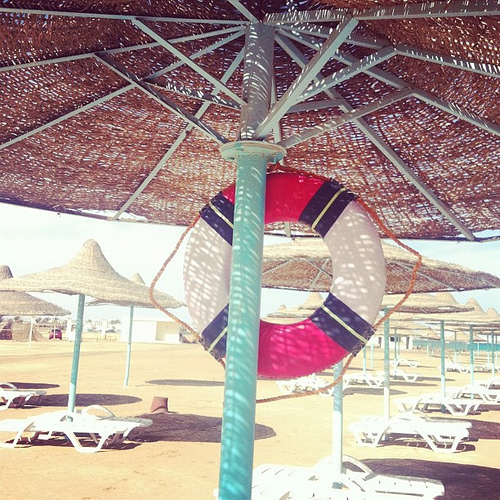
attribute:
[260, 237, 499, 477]
umbrella — for beach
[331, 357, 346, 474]
pole — blue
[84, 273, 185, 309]
umbrella — for beach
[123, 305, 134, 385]
pole — blue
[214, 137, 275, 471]
pole — blue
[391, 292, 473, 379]
umbrella — for beach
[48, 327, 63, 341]
car — red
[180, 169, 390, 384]
wreath — white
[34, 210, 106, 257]
sky — blue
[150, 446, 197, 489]
ground — brown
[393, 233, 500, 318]
sky — cloudy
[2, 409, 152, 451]
chair — lounge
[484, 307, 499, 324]
umbrella — for beach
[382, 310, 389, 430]
pole — blue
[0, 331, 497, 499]
beach — sandy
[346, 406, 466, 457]
chair — lounge